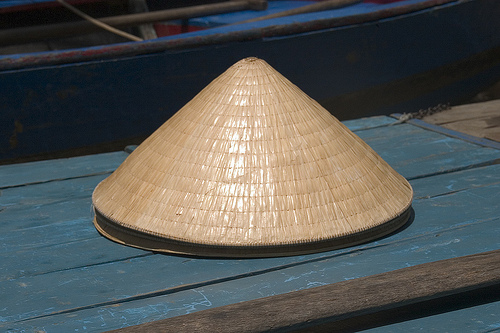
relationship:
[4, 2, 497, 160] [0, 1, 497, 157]
boat with paint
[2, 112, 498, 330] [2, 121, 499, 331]
wooden table with slats